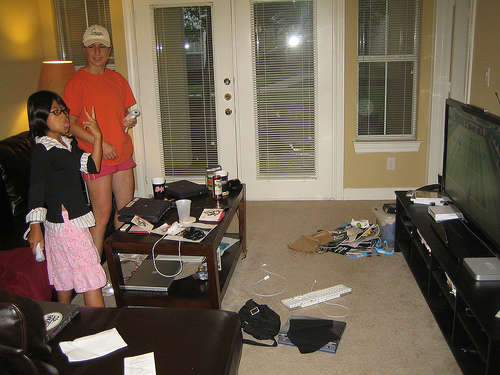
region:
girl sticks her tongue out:
[35, 92, 116, 172]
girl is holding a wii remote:
[10, 211, 69, 269]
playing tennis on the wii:
[426, 111, 496, 252]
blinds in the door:
[248, 4, 350, 193]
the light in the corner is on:
[20, 53, 88, 144]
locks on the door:
[219, 74, 244, 134]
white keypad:
[248, 282, 401, 327]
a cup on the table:
[169, 196, 204, 237]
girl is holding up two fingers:
[52, 95, 130, 166]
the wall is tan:
[343, 145, 432, 191]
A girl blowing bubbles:
[19, 75, 129, 284]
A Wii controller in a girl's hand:
[20, 214, 68, 277]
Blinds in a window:
[353, 51, 419, 154]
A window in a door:
[241, 19, 330, 189]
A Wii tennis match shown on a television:
[429, 88, 491, 214]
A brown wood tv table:
[382, 183, 495, 363]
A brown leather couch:
[1, 288, 247, 367]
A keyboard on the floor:
[284, 268, 359, 314]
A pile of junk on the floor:
[296, 202, 387, 261]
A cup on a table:
[165, 189, 203, 233]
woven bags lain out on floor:
[279, 196, 386, 263]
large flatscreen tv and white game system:
[439, 131, 494, 228]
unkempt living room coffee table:
[131, 134, 227, 259]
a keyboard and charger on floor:
[231, 259, 384, 371]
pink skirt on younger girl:
[40, 207, 100, 289]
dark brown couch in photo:
[10, 311, 231, 366]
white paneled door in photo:
[154, 16, 254, 170]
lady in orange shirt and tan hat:
[57, 29, 124, 170]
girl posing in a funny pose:
[17, 93, 125, 293]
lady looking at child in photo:
[44, 30, 207, 175]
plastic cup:
[171, 193, 197, 223]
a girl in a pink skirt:
[20, 90, 100, 305]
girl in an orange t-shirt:
[60, 22, 140, 222]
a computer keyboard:
[275, 272, 360, 317]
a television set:
[438, 91, 499, 255]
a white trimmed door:
[135, 1, 239, 195]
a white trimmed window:
[354, 1, 428, 156]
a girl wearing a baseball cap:
[56, 25, 146, 227]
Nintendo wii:
[426, 201, 460, 221]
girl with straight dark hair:
[15, 88, 89, 154]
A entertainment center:
[394, 88, 499, 370]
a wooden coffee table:
[103, 173, 251, 303]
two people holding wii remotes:
[18, 49, 145, 306]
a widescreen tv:
[442, 98, 496, 253]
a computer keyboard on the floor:
[280, 267, 354, 315]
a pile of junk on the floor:
[291, 211, 391, 263]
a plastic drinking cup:
[172, 193, 194, 222]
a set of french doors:
[128, 48, 327, 193]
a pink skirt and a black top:
[29, 130, 106, 295]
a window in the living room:
[356, 53, 418, 145]